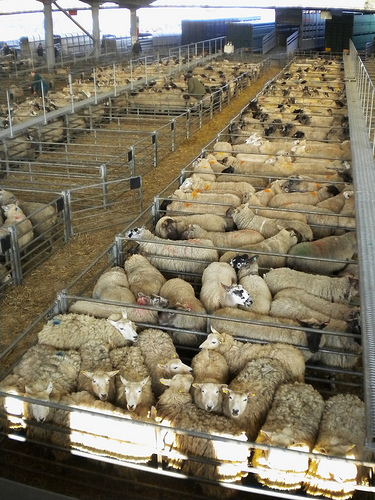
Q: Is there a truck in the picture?
A: Yes, there is a truck.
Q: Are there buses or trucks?
A: Yes, there is a truck.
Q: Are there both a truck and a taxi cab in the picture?
A: No, there is a truck but no taxis.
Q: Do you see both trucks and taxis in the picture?
A: No, there is a truck but no taxis.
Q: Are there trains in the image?
A: No, there are no trains.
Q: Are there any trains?
A: No, there are no trains.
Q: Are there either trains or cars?
A: No, there are no trains or cars.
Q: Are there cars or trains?
A: No, there are no trains or cars.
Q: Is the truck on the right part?
A: Yes, the truck is on the right of the image.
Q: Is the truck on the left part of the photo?
A: No, the truck is on the right of the image.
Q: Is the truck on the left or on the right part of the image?
A: The truck is on the right of the image.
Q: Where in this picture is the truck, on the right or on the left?
A: The truck is on the right of the image.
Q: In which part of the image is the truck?
A: The truck is on the right of the image.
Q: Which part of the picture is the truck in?
A: The truck is on the right of the image.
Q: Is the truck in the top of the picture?
A: Yes, the truck is in the top of the image.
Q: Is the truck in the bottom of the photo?
A: No, the truck is in the top of the image.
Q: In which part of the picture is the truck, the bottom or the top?
A: The truck is in the top of the image.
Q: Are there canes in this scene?
A: No, there are no canes.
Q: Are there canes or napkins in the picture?
A: No, there are no canes or napkins.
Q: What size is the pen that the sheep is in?
A: The pen is small.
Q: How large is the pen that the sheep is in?
A: The pen is small.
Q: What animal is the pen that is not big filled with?
A: The pen is filled with sheep.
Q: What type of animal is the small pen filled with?
A: The pen is filled with sheep.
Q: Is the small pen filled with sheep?
A: Yes, the pen is filled with sheep.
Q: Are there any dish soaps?
A: No, there are no dish soaps.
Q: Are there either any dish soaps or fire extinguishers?
A: No, there are no dish soaps or fire extinguishers.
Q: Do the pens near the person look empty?
A: Yes, the pens are empty.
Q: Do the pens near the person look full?
A: No, the pens are empty.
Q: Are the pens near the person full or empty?
A: The pens are empty.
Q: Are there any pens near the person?
A: Yes, there are pens near the person.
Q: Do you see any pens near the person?
A: Yes, there are pens near the person.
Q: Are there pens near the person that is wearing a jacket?
A: Yes, there are pens near the person.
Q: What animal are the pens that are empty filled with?
A: The pens are filled with sheep.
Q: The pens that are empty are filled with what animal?
A: The pens are filled with sheep.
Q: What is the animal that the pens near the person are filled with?
A: The animal is a sheep.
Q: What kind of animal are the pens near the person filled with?
A: The pens are filled with sheep.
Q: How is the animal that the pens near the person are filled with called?
A: The animal is a sheep.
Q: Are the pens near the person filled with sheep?
A: Yes, the pens are filled with sheep.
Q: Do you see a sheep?
A: Yes, there is a sheep.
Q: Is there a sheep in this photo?
A: Yes, there is a sheep.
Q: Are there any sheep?
A: Yes, there is a sheep.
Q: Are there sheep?
A: Yes, there is a sheep.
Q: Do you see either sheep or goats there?
A: Yes, there is a sheep.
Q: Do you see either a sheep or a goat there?
A: Yes, there is a sheep.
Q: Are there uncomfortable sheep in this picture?
A: Yes, there is an uncomfortable sheep.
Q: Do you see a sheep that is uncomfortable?
A: Yes, there is a sheep that is uncomfortable.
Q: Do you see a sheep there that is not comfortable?
A: Yes, there is a uncomfortable sheep.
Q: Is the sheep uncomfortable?
A: Yes, the sheep is uncomfortable.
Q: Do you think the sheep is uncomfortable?
A: Yes, the sheep is uncomfortable.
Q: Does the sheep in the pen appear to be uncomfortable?
A: Yes, the sheep is uncomfortable.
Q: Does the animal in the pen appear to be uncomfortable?
A: Yes, the sheep is uncomfortable.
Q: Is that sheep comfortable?
A: No, the sheep is uncomfortable.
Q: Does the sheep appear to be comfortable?
A: No, the sheep is uncomfortable.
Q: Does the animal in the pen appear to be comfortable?
A: No, the sheep is uncomfortable.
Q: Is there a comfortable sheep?
A: No, there is a sheep but it is uncomfortable.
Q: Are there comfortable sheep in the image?
A: No, there is a sheep but it is uncomfortable.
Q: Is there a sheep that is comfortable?
A: No, there is a sheep but it is uncomfortable.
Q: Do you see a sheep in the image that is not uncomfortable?
A: No, there is a sheep but it is uncomfortable.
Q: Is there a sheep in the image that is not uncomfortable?
A: No, there is a sheep but it is uncomfortable.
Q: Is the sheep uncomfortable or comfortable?
A: The sheep is uncomfortable.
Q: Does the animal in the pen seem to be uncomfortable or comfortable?
A: The sheep is uncomfortable.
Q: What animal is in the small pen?
A: The animal is a sheep.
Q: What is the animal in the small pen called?
A: The animal is a sheep.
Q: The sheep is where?
A: The sheep is in the pen.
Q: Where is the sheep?
A: The sheep is in the pen.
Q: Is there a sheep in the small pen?
A: Yes, there is a sheep in the pen.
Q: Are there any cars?
A: No, there are no cars.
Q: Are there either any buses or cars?
A: No, there are no cars or buses.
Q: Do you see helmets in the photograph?
A: No, there are no helmets.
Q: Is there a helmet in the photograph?
A: No, there are no helmets.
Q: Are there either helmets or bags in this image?
A: No, there are no helmets or bags.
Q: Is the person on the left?
A: Yes, the person is on the left of the image.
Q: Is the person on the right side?
A: No, the person is on the left of the image.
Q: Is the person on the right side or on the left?
A: The person is on the left of the image.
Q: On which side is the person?
A: The person is on the left of the image.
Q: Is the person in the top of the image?
A: Yes, the person is in the top of the image.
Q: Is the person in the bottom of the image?
A: No, the person is in the top of the image.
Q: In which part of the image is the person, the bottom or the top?
A: The person is in the top of the image.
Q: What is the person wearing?
A: The person is wearing a jacket.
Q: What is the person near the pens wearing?
A: The person is wearing a jacket.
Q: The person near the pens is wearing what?
A: The person is wearing a jacket.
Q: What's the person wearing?
A: The person is wearing a jacket.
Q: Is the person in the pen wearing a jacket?
A: Yes, the person is wearing a jacket.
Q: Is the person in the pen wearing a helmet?
A: No, the person is wearing a jacket.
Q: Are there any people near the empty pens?
A: Yes, there is a person near the pens.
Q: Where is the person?
A: The person is in the pen.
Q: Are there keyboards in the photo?
A: No, there are no keyboards.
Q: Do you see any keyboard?
A: No, there are no keyboards.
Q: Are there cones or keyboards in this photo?
A: No, there are no keyboards or cones.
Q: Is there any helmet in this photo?
A: No, there are no helmets.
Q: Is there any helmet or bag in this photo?
A: No, there are no helmets or bags.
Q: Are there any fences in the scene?
A: Yes, there is a fence.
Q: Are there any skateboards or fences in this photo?
A: Yes, there is a fence.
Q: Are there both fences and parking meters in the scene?
A: No, there is a fence but no parking meters.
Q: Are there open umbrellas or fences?
A: Yes, there is an open fence.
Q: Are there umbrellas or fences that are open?
A: Yes, the fence is open.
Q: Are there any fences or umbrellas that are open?
A: Yes, the fence is open.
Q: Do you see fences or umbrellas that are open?
A: Yes, the fence is open.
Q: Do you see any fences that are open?
A: Yes, there is an open fence.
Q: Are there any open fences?
A: Yes, there is an open fence.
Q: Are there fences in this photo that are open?
A: Yes, there is a fence that is open.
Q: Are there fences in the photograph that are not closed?
A: Yes, there is a open fence.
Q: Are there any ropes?
A: No, there are no ropes.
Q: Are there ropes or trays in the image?
A: No, there are no ropes or trays.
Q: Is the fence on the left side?
A: Yes, the fence is on the left of the image.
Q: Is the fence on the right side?
A: No, the fence is on the left of the image.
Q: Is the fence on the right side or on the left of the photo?
A: The fence is on the left of the image.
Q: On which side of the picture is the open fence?
A: The fence is on the left of the image.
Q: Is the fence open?
A: Yes, the fence is open.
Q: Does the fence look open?
A: Yes, the fence is open.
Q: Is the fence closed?
A: No, the fence is open.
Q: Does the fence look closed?
A: No, the fence is open.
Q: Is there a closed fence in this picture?
A: No, there is a fence but it is open.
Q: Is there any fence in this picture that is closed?
A: No, there is a fence but it is open.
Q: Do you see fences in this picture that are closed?
A: No, there is a fence but it is open.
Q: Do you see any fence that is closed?
A: No, there is a fence but it is open.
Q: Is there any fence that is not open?
A: No, there is a fence but it is open.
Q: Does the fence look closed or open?
A: The fence is open.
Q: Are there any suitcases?
A: No, there are no suitcases.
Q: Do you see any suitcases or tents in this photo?
A: No, there are no suitcases or tents.